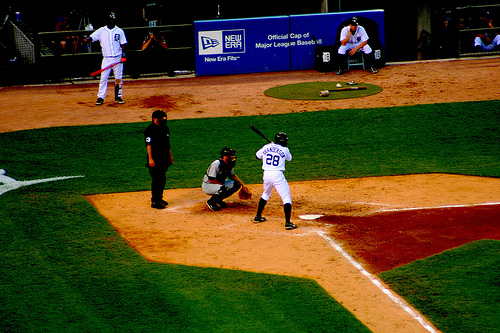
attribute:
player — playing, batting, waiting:
[255, 130, 298, 232]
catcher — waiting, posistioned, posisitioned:
[201, 144, 248, 212]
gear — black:
[216, 159, 234, 186]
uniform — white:
[90, 25, 130, 100]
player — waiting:
[80, 9, 129, 106]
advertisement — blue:
[194, 13, 335, 76]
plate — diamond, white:
[298, 212, 325, 222]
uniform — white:
[256, 143, 292, 206]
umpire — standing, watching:
[144, 107, 172, 210]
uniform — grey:
[201, 156, 222, 193]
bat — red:
[90, 60, 123, 77]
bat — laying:
[326, 87, 369, 93]